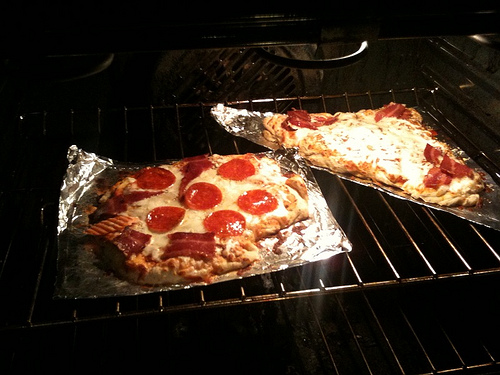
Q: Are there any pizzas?
A: Yes, there is a pizza.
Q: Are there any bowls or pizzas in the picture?
A: Yes, there is a pizza.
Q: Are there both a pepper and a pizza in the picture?
A: No, there is a pizza but no peppers.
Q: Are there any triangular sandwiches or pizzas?
A: Yes, there is a triangular pizza.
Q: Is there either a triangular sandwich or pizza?
A: Yes, there is a triangular pizza.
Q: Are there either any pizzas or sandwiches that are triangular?
A: Yes, the pizza is triangular.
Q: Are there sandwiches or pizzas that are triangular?
A: Yes, the pizza is triangular.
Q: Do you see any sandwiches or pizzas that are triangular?
A: Yes, the pizza is triangular.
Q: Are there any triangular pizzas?
A: Yes, there is a triangular pizza.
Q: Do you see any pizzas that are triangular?
A: Yes, there is a triangular pizza.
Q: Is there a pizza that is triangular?
A: Yes, there is a pizza that is triangular.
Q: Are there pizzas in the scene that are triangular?
A: Yes, there is a pizza that is triangular.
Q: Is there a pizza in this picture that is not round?
A: Yes, there is a triangular pizza.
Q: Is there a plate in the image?
A: No, there are no plates.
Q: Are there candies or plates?
A: No, there are no plates or candies.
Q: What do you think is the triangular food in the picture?
A: The food is a pizza.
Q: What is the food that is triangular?
A: The food is a pizza.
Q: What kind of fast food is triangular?
A: The fast food is a pizza.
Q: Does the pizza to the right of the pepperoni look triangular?
A: Yes, the pizza is triangular.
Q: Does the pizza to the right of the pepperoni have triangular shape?
A: Yes, the pizza is triangular.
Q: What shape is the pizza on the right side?
A: The pizza is triangular.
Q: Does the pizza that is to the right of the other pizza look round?
A: No, the pizza is triangular.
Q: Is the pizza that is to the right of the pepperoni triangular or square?
A: The pizza is triangular.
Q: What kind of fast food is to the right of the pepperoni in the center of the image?
A: The food is a pizza.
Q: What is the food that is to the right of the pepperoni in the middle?
A: The food is a pizza.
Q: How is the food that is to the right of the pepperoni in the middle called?
A: The food is a pizza.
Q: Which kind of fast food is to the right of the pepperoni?
A: The food is a pizza.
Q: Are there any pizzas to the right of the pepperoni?
A: Yes, there is a pizza to the right of the pepperoni.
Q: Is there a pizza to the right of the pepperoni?
A: Yes, there is a pizza to the right of the pepperoni.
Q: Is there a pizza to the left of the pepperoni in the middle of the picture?
A: No, the pizza is to the right of the pepperoni.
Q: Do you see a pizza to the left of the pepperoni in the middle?
A: No, the pizza is to the right of the pepperoni.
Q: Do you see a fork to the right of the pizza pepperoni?
A: No, there is a pizza to the right of the pepperoni.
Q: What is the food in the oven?
A: The food is a pizza.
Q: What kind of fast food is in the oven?
A: The food is a pizza.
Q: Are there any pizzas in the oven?
A: Yes, there is a pizza in the oven.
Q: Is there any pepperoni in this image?
A: Yes, there is pepperoni.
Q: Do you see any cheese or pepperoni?
A: Yes, there is pepperoni.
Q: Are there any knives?
A: No, there are no knives.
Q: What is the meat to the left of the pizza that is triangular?
A: The meat is pepperoni.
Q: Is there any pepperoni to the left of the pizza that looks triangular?
A: Yes, there is pepperoni to the left of the pizza.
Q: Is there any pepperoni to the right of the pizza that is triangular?
A: No, the pepperoni is to the left of the pizza.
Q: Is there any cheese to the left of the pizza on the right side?
A: No, there is pepperoni to the left of the pizza.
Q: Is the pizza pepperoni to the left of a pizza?
A: Yes, the pepperoni is to the left of a pizza.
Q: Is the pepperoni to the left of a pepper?
A: No, the pepperoni is to the left of a pizza.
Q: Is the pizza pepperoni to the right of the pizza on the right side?
A: No, the pepperoni is to the left of the pizza.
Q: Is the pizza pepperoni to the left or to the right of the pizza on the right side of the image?
A: The pepperoni is to the left of the pizza.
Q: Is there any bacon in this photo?
A: Yes, there is bacon.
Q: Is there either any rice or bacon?
A: Yes, there is bacon.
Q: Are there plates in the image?
A: No, there are no plates.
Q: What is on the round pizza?
A: The bacon is on the pizza.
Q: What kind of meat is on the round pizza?
A: The meat is bacon.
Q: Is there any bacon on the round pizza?
A: Yes, there is bacon on the pizza.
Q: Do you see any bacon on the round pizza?
A: Yes, there is bacon on the pizza.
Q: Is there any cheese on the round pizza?
A: No, there is bacon on the pizza.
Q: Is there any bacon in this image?
A: Yes, there is bacon.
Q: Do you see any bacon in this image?
A: Yes, there is bacon.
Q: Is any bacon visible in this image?
A: Yes, there is bacon.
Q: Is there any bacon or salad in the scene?
A: Yes, there is bacon.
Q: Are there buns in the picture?
A: No, there are no buns.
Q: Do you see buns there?
A: No, there are no buns.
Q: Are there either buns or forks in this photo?
A: No, there are no buns or forks.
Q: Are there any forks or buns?
A: No, there are no buns or forks.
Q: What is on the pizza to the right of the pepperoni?
A: The bacon is on the pizza.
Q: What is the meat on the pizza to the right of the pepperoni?
A: The meat is bacon.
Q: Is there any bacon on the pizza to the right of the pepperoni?
A: Yes, there is bacon on the pizza.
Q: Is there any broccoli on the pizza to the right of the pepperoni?
A: No, there is bacon on the pizza.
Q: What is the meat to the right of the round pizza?
A: The meat is bacon.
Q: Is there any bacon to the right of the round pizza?
A: Yes, there is bacon to the right of the pizza.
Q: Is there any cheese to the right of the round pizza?
A: No, there is bacon to the right of the pizza.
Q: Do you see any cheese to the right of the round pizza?
A: No, there is bacon to the right of the pizza.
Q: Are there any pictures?
A: No, there are no pictures.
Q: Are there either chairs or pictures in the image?
A: No, there are no pictures or chairs.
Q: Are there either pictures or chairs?
A: No, there are no pictures or chairs.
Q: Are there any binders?
A: No, there are no binders.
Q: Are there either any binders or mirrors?
A: No, there are no binders or mirrors.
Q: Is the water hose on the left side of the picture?
A: Yes, the water hose is on the left of the image.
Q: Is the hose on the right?
A: No, the hose is on the left of the image.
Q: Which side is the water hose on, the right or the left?
A: The water hose is on the left of the image.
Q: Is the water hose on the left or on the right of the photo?
A: The water hose is on the left of the image.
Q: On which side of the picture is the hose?
A: The hose is on the left of the image.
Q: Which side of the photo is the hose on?
A: The hose is on the left of the image.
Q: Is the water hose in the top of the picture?
A: Yes, the water hose is in the top of the image.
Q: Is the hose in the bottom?
A: No, the hose is in the top of the image.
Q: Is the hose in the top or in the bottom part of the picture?
A: The hose is in the top of the image.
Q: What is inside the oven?
A: The hose is inside the oven.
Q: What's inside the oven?
A: The hose is inside the oven.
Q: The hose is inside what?
A: The hose is inside the oven.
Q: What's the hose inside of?
A: The hose is inside the oven.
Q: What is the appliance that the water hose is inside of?
A: The appliance is an oven.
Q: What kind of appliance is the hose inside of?
A: The water hose is inside the oven.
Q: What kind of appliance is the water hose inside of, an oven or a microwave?
A: The water hose is inside an oven.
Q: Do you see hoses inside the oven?
A: Yes, there is a hose inside the oven.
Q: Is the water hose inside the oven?
A: Yes, the water hose is inside the oven.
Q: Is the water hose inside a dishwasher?
A: No, the water hose is inside the oven.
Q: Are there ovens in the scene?
A: Yes, there is an oven.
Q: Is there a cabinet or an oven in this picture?
A: Yes, there is an oven.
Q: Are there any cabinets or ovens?
A: Yes, there is an oven.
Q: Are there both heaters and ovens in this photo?
A: No, there is an oven but no heaters.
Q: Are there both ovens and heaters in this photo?
A: No, there is an oven but no heaters.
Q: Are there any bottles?
A: No, there are no bottles.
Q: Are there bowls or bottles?
A: No, there are no bottles or bowls.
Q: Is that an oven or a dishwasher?
A: That is an oven.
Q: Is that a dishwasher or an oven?
A: That is an oven.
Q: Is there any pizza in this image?
A: Yes, there is a pizza.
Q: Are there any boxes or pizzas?
A: Yes, there is a pizza.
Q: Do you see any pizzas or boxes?
A: Yes, there is a pizza.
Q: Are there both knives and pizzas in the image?
A: No, there is a pizza but no knives.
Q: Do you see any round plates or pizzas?
A: Yes, there is a round pizza.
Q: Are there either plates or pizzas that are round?
A: Yes, the pizza is round.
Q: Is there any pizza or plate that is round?
A: Yes, the pizza is round.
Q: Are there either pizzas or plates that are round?
A: Yes, the pizza is round.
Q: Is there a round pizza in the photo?
A: Yes, there is a round pizza.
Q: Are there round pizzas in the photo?
A: Yes, there is a round pizza.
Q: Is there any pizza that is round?
A: Yes, there is a pizza that is round.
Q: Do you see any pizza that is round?
A: Yes, there is a pizza that is round.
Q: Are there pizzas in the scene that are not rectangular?
A: Yes, there is a round pizza.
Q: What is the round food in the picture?
A: The food is a pizza.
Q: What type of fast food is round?
A: The fast food is a pizza.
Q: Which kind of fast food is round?
A: The fast food is a pizza.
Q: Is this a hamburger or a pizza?
A: This is a pizza.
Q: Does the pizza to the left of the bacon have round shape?
A: Yes, the pizza is round.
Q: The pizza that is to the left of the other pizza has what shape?
A: The pizza is round.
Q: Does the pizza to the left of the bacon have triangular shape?
A: No, the pizza is round.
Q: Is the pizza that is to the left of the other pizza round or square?
A: The pizza is round.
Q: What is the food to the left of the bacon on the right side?
A: The food is a pizza.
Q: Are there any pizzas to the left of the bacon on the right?
A: Yes, there is a pizza to the left of the bacon.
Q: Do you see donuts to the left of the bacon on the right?
A: No, there is a pizza to the left of the bacon.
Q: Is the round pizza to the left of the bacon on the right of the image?
A: Yes, the pizza is to the left of the bacon.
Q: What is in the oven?
A: The pizza is in the oven.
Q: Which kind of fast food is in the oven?
A: The food is a pizza.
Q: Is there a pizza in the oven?
A: Yes, there is a pizza in the oven.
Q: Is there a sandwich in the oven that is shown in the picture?
A: No, there is a pizza in the oven.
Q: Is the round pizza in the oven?
A: Yes, the pizza is in the oven.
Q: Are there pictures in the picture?
A: No, there are no pictures.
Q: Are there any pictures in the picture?
A: No, there are no pictures.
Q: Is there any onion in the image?
A: No, there are no onions.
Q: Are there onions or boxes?
A: No, there are no onions or boxes.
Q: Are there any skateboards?
A: No, there are no skateboards.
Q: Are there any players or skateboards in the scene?
A: No, there are no skateboards or players.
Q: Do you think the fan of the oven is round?
A: Yes, the fan is round.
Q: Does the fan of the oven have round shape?
A: Yes, the fan is round.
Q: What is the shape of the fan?
A: The fan is round.